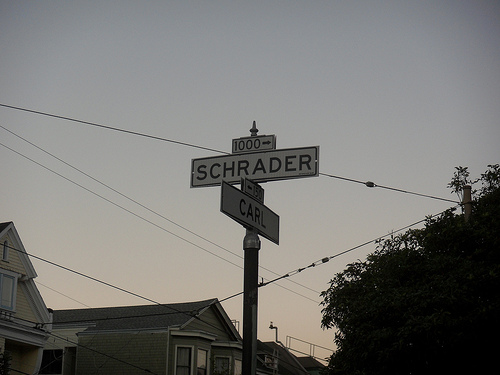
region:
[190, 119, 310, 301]
set of four road signs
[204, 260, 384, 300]
telephone pole wire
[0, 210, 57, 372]
single yellow house standing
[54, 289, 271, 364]
single yellow house standing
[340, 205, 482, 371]
groups of green trees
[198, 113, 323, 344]
street pole with signs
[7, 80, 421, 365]
telephone wires going to houses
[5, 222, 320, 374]
sets of houses on street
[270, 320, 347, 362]
metal signal searcher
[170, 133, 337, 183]
numbers located on street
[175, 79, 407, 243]
schrader and carl streets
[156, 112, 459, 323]
the sky is dusk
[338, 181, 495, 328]
the trees are in shadow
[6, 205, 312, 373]
there are three houses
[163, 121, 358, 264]
the text is black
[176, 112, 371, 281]
schrader street block 1000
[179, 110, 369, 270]
the signs are white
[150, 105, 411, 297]
wires behind the sign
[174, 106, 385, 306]
the street signs are on a pole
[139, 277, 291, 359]
the house has bay windows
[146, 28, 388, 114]
this is the sky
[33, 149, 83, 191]
these are the wires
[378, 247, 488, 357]
this is a tree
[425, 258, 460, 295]
the tree has green leaves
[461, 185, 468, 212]
this is a pole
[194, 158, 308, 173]
this is a writing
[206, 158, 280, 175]
the writing is in black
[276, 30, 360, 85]
the sky is blue in color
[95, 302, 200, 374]
this is a building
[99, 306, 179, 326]
this is the roof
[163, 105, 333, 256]
a white street sign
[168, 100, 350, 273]
street sign for schrader and carl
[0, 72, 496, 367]
a small town intersection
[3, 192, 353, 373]
a neighborhood of houses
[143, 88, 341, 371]
a tall metal sign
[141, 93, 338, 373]
a metal street sign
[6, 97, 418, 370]
a metal intersection sign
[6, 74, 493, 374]
a small town at sunset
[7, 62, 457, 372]
a line of houses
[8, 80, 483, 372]
a street sign with houses behind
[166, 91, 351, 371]
signs for Schrader and Carl intersection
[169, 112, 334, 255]
two white street signs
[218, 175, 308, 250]
sign with black text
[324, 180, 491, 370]
green hedge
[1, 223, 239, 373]
two yellow houses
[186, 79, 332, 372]
white street signs with black text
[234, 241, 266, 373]
a grey sign post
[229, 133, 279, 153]
sign for the 1000 block of a street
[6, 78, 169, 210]
power lines on a dusk sky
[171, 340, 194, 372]
window with white curtains